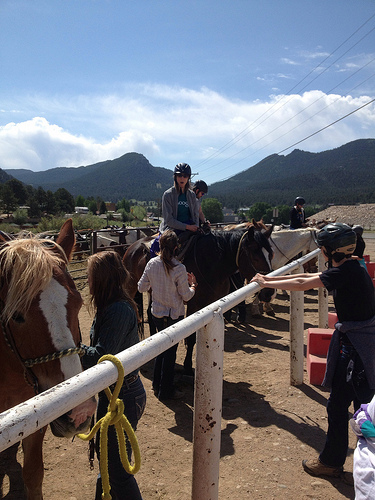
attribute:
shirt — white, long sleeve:
[138, 253, 193, 316]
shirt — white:
[137, 256, 194, 318]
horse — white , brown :
[2, 225, 89, 499]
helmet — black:
[170, 156, 196, 177]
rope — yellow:
[78, 345, 142, 495]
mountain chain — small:
[9, 152, 323, 197]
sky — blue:
[64, 25, 242, 59]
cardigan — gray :
[162, 178, 202, 232]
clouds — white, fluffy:
[2, 84, 374, 153]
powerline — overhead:
[191, 25, 362, 172]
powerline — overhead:
[191, 56, 363, 176]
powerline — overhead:
[190, 70, 362, 180]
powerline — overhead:
[206, 93, 362, 185]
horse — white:
[251, 224, 322, 316]